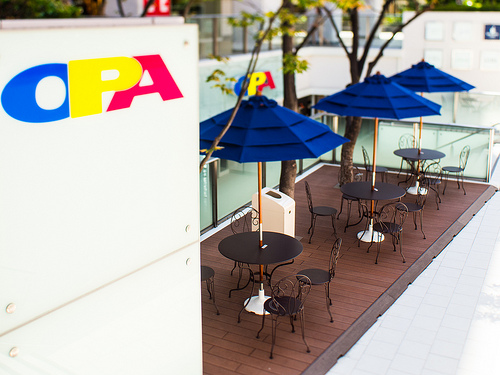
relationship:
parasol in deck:
[309, 71, 442, 121] [201, 160, 491, 371]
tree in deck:
[340, 107, 363, 184] [220, 156, 469, 370]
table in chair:
[215, 220, 299, 279] [255, 277, 307, 354]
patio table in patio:
[303, 154, 435, 281] [179, 135, 481, 373]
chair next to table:
[255, 274, 310, 359] [218, 231, 303, 322]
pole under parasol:
[258, 162, 263, 249] [198, 93, 348, 165]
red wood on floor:
[341, 267, 376, 300] [221, 301, 260, 372]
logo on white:
[9, 48, 225, 156] [205, 74, 235, 104]